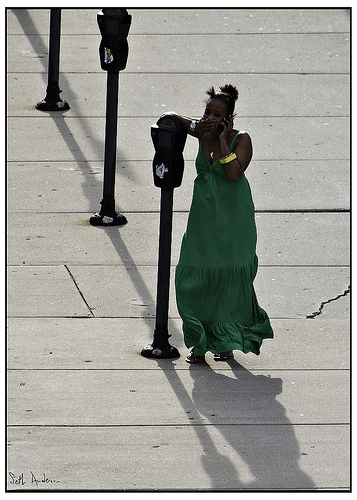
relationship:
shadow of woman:
[180, 355, 313, 492] [172, 81, 275, 366]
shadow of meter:
[112, 231, 145, 306] [93, 6, 133, 231]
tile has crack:
[250, 264, 352, 319] [305, 281, 349, 328]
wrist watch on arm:
[192, 119, 198, 135] [171, 114, 201, 133]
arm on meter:
[171, 114, 201, 133] [146, 116, 188, 363]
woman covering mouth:
[172, 81, 275, 366] [206, 120, 219, 130]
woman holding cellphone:
[172, 81, 275, 366] [218, 110, 235, 131]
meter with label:
[93, 6, 133, 231] [102, 48, 112, 64]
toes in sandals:
[188, 356, 196, 361] [184, 347, 203, 362]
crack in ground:
[305, 281, 349, 328] [6, 14, 352, 494]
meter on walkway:
[93, 6, 133, 231] [6, 14, 352, 494]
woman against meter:
[172, 81, 275, 366] [93, 6, 133, 231]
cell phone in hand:
[216, 117, 232, 133] [219, 114, 236, 135]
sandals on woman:
[190, 350, 237, 365] [172, 81, 275, 366]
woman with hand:
[172, 81, 275, 366] [219, 114, 236, 135]